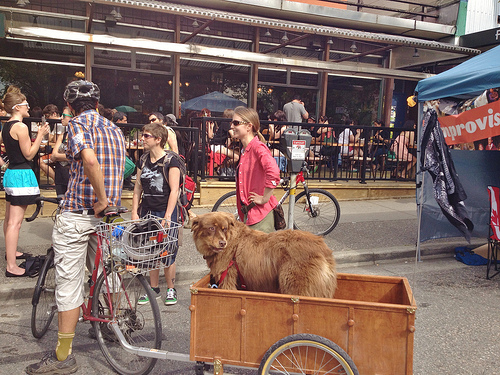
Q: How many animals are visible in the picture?
A: One.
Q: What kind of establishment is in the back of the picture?
A: A restaurant.